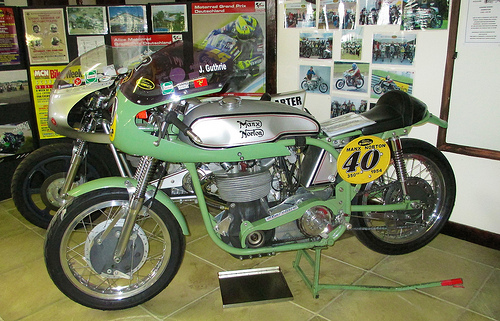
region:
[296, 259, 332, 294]
part of a stand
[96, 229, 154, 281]
rim of the front wheel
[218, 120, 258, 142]
part of a tank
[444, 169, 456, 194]
part of a rubber tubing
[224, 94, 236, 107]
lid of the tank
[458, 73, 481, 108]
part of a notice board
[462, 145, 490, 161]
part of a wooden edge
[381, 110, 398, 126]
part of a rare seat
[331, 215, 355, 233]
part of the left pedal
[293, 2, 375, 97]
part of some pictures of motorbikes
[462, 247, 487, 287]
part of the floor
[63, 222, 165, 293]
front wheel of the bike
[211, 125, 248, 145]
part of a tank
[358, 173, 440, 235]
rare wheel of the bike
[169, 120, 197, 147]
left gear of the motorbike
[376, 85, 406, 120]
rare passenger black seat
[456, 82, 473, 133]
part of a notice board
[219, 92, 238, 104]
lid of the tank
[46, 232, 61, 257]
part of a rubber tube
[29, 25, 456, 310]
a green motorcycle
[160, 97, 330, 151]
a silver gas tank on a motorcycle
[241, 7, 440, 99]
pictures on the wall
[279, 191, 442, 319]
a stand for a motorcycle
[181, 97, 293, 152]
black writing on a motorcycle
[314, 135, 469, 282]
a rear wheel on a motorcycle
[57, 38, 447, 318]
two motorcycles on display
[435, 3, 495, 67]
a sign on the wall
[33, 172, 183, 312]
the front wheel of a motorcycle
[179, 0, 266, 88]
picture of a person riding a motorcycle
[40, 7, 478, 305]
motorcycles in a showroom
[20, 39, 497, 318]
two motorcycles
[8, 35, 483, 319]
motorcyles on display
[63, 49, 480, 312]
the green motorcyle has a yellow plate on it with the number forty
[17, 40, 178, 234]
a silver motorcyle is behind the green motorcyle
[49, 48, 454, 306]
a green motorcyle with a silver gas tank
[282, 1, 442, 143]
pictures of people on motorcyles are on the window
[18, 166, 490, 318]
the floor is tan colored tile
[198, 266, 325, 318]
a metal pan is on the floor under a motorcyle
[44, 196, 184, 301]
this is a black tyre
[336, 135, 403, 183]
this is a label on the rear wheel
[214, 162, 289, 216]
this is the engine of the motor bike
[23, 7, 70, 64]
this is a picture on the wall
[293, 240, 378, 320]
this is the motor bike stand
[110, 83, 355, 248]
the motor bike is green in color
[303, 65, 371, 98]
these are pictures of people on the motorbike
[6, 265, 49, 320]
this is the floor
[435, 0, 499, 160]
this is a notice board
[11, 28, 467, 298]
these are motor bikes